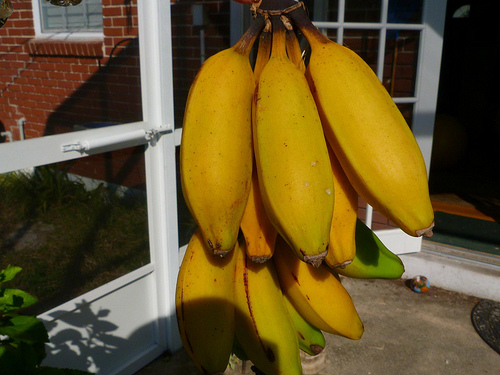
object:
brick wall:
[0, 0, 423, 207]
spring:
[62, 123, 174, 157]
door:
[2, 0, 166, 375]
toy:
[408, 274, 430, 294]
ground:
[141, 276, 500, 375]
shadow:
[0, 298, 134, 375]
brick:
[24, 34, 106, 58]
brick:
[0, 0, 37, 135]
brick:
[22, 60, 113, 144]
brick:
[103, 0, 141, 122]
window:
[30, 0, 103, 38]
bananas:
[175, 0, 433, 374]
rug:
[470, 298, 500, 360]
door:
[292, 0, 446, 260]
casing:
[0, 0, 137, 141]